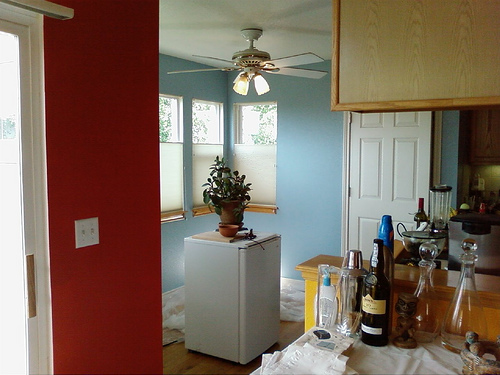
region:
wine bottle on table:
[327, 240, 389, 370]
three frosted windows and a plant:
[152, 130, 286, 217]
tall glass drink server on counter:
[440, 228, 480, 357]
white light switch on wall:
[58, 197, 112, 287]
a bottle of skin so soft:
[295, 245, 333, 355]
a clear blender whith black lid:
[404, 158, 461, 265]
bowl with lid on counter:
[377, 206, 451, 276]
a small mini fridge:
[175, 229, 293, 372]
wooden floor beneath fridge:
[193, 310, 295, 373]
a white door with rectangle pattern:
[247, 130, 434, 304]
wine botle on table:
[348, 237, 392, 373]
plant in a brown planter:
[181, 160, 266, 267]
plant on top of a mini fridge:
[188, 124, 283, 335]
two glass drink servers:
[401, 235, 484, 356]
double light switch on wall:
[62, 200, 122, 277]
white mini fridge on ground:
[165, 222, 285, 360]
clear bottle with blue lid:
[292, 256, 340, 351]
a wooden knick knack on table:
[365, 283, 425, 370]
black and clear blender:
[396, 176, 459, 251]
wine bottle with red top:
[391, 189, 426, 251]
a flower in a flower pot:
[196, 142, 264, 269]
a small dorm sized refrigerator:
[180, 217, 310, 372]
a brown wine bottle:
[332, 236, 407, 362]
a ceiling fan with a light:
[169, 16, 331, 114]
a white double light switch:
[53, 202, 115, 269]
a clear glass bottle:
[440, 237, 479, 365]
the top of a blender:
[426, 175, 462, 240]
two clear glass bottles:
[409, 230, 481, 345]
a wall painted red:
[53, 33, 146, 322]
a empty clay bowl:
[213, 212, 244, 251]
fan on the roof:
[191, 21, 323, 106]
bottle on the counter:
[338, 236, 409, 333]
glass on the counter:
[400, 241, 452, 294]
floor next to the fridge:
[168, 354, 200, 374]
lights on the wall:
[55, 200, 125, 267]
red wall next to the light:
[68, 275, 135, 327]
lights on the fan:
[213, 63, 280, 101]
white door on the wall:
[328, 133, 416, 208]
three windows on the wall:
[150, 108, 270, 145]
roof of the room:
[183, 8, 228, 37]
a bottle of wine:
[357, 239, 394, 346]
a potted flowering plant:
[200, 151, 247, 227]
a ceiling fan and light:
[168, 23, 326, 105]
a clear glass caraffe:
[408, 236, 440, 341]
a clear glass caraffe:
[439, 234, 484, 352]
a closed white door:
[345, 105, 428, 259]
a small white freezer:
[183, 223, 285, 363]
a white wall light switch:
[70, 214, 100, 251]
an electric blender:
[428, 182, 450, 231]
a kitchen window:
[232, 99, 280, 208]